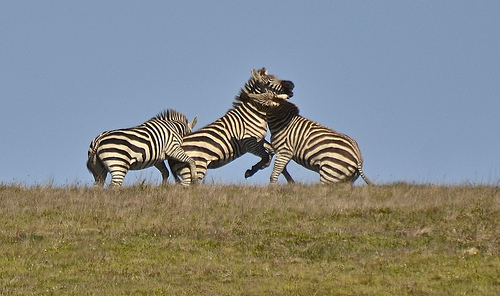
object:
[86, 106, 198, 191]
zebras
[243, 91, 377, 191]
zebra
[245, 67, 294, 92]
heads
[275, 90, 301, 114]
mane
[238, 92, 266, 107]
snout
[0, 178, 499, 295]
grass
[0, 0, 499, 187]
sky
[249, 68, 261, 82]
ear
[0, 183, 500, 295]
hill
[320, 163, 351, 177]
stripes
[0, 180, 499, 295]
area